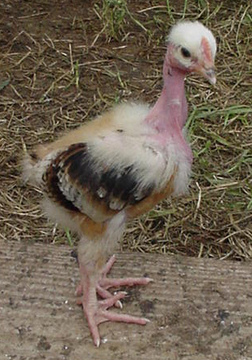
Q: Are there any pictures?
A: No, there are no pictures.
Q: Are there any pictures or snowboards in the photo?
A: No, there are no pictures or snowboards.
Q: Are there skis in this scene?
A: No, there are no skis.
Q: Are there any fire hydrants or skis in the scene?
A: No, there are no skis or fire hydrants.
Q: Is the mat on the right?
A: Yes, the mat is on the right of the image.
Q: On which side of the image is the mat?
A: The mat is on the right of the image.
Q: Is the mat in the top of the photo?
A: No, the mat is in the bottom of the image.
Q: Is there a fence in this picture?
A: No, there are no fences.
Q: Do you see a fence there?
A: No, there are no fences.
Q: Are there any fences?
A: No, there are no fences.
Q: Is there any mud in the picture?
A: Yes, there is mud.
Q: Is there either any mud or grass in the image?
A: Yes, there is mud.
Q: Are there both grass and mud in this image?
A: Yes, there are both mud and grass.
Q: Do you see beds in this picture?
A: No, there are no beds.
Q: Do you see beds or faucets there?
A: No, there are no beds or faucets.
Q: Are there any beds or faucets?
A: No, there are no beds or faucets.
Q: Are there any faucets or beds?
A: No, there are no beds or faucets.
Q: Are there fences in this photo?
A: No, there are no fences.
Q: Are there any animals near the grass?
A: Yes, there is an animal near the grass.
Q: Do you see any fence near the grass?
A: No, there is an animal near the grass.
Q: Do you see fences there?
A: No, there are no fences.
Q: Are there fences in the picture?
A: No, there are no fences.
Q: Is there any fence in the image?
A: No, there are no fences.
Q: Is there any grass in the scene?
A: Yes, there is grass.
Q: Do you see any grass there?
A: Yes, there is grass.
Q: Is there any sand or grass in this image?
A: Yes, there is grass.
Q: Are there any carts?
A: No, there are no carts.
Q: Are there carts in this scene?
A: No, there are no carts.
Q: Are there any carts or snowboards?
A: No, there are no carts or snowboards.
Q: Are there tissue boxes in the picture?
A: No, there are no tissue boxes.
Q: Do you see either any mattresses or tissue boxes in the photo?
A: No, there are no tissue boxes or mattresses.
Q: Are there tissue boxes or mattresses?
A: No, there are no tissue boxes or mattresses.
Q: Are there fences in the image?
A: No, there are no fences.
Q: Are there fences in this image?
A: No, there are no fences.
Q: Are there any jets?
A: No, there are no jets.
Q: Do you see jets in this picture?
A: No, there are no jets.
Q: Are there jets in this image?
A: No, there are no jets.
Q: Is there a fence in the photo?
A: No, there are no fences.